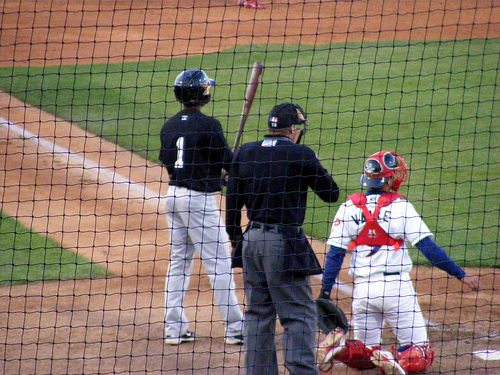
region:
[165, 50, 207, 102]
player has black helmet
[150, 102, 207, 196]
black and white shirt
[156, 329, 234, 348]
black and white shoes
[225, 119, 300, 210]
umpire has black shirt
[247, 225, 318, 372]
umpire has grey pants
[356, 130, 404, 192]
red and blue helmet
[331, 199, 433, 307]
blue and white shirt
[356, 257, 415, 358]
catcher has white pants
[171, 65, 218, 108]
Black baseball helmet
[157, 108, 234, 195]
Black and white shirt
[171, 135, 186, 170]
White number on black shirt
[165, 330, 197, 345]
Black and white shoe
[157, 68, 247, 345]
Baseball player wearing black and white shirt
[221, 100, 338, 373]
Man wearing black shirt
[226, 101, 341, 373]
Man wearing grey pants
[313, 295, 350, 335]
Black baseball glove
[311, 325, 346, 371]
White and red shoes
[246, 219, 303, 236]
Black belt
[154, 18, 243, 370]
A person playing baseball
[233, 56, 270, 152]
A wooden baseball racket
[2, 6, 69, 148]
A brow and green baseball court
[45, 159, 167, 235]
A brow baseball court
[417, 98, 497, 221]
A green baseball court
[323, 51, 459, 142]
A green baseball court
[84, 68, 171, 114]
A green baseball court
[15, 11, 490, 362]
black netting in back of players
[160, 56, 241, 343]
player wearing black and white uniform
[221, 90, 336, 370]
umpire in dark outfit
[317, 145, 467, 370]
catcher wearing red, white and blue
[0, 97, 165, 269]
white stripe on brown dirt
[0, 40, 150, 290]
corners of green grass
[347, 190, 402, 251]
X-shape across player's back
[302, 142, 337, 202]
elbow bent in black sleeve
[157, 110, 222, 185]
single digit on back of shirt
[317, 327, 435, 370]
soles of shoes on bent knees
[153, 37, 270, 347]
batter holding a bat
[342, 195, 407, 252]
red straps across the back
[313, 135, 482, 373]
catcher kneeling in the dirt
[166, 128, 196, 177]
white number on the back of the jersey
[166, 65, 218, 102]
helmet on the head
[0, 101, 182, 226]
white line in the dirt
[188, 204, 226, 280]
wrinkles on the pants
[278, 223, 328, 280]
black pouch hanging from the hip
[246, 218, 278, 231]
black belt running through the gray belt loops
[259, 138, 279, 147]
logo on the back of the shirt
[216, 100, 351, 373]
The person making the official calls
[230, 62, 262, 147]
a dark brown baseball bat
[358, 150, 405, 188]
a red and blue protective helmet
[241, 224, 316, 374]
a pair of grey pants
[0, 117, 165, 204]
a white foul line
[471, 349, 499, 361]
a baseball home plate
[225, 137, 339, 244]
a dark blue long sleeve shirt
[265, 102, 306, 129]
a black cap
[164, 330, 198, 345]
a blue and white athletic shoe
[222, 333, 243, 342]
a blue and white athletic shoe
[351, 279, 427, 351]
a pair of white pants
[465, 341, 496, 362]
A white baseball plate.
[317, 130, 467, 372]
a person on their knees in the dirt.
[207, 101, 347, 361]
An umpire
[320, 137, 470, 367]
A baseball catcher